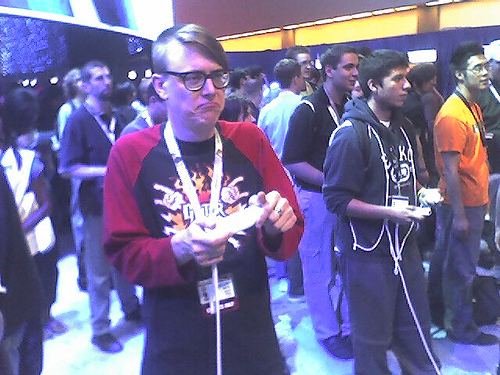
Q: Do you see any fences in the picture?
A: No, there are no fences.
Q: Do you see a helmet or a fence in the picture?
A: No, there are no fences or helmets.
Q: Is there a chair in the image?
A: No, there are no chairs.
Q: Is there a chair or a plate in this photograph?
A: No, there are no chairs or plates.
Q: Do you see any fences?
A: No, there are no fences.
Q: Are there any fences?
A: No, there are no fences.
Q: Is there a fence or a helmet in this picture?
A: No, there are no fences or helmets.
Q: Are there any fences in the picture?
A: No, there are no fences.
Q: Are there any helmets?
A: No, there are no helmets.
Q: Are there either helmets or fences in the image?
A: No, there are no helmets or fences.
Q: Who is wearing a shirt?
A: The man is wearing a shirt.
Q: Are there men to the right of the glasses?
A: Yes, there is a man to the right of the glasses.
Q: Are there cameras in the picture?
A: Yes, there is a camera.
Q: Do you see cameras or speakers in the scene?
A: Yes, there is a camera.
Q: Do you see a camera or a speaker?
A: Yes, there is a camera.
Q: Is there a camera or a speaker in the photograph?
A: Yes, there is a camera.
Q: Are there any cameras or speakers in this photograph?
A: Yes, there is a camera.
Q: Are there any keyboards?
A: No, there are no keyboards.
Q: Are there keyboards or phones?
A: No, there are no keyboards or phones.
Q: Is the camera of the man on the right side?
A: Yes, the camera is on the right of the image.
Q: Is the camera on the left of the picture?
A: No, the camera is on the right of the image.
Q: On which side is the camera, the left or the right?
A: The camera is on the right of the image.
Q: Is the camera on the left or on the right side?
A: The camera is on the right of the image.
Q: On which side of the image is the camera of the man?
A: The camera is on the right of the image.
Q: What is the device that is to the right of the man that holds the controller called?
A: The device is a camera.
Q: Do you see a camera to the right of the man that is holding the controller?
A: Yes, there is a camera to the right of the man.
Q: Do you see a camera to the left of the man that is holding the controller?
A: No, the camera is to the right of the man.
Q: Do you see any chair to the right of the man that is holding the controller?
A: No, there is a camera to the right of the man.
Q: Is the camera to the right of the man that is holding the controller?
A: Yes, the camera is to the right of the man.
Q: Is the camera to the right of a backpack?
A: No, the camera is to the right of the man.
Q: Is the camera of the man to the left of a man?
A: No, the camera is to the right of a man.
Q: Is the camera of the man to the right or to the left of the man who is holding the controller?
A: The camera is to the right of the man.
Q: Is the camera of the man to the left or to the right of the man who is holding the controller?
A: The camera is to the right of the man.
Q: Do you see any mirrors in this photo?
A: No, there are no mirrors.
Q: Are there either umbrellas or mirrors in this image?
A: No, there are no mirrors or umbrellas.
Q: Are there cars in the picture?
A: No, there are no cars.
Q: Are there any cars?
A: No, there are no cars.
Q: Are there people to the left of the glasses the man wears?
A: Yes, there are people to the left of the glasses.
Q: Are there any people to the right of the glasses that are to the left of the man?
A: No, the people are to the left of the glasses.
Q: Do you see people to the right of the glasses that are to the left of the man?
A: No, the people are to the left of the glasses.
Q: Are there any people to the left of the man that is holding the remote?
A: Yes, there are people to the left of the man.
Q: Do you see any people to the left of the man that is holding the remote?
A: Yes, there are people to the left of the man.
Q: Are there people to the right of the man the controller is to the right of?
A: No, the people are to the left of the man.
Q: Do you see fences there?
A: No, there are no fences.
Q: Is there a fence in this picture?
A: No, there are no fences.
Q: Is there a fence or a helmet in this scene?
A: No, there are no fences or helmets.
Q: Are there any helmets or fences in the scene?
A: No, there are no fences or helmets.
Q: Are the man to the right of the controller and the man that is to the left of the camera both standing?
A: Yes, both the man and the man are standing.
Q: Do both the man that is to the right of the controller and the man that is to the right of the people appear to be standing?
A: Yes, both the man and the man are standing.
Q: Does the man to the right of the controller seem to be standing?
A: Yes, the man is standing.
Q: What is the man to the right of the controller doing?
A: The man is standing.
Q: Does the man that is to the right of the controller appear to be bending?
A: No, the man is standing.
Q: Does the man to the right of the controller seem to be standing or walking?
A: The man is standing.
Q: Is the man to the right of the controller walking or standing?
A: The man is standing.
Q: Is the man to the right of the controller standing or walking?
A: The man is standing.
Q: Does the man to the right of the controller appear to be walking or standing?
A: The man is standing.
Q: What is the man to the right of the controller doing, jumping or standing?
A: The man is standing.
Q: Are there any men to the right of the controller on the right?
A: Yes, there is a man to the right of the controller.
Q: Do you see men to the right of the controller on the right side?
A: Yes, there is a man to the right of the controller.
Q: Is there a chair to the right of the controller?
A: No, there is a man to the right of the controller.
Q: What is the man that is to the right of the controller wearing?
A: The man is wearing a shirt.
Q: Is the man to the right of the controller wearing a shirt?
A: Yes, the man is wearing a shirt.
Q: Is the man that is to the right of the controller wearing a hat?
A: No, the man is wearing a shirt.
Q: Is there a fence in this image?
A: No, there are no fences.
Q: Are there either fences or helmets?
A: No, there are no fences or helmets.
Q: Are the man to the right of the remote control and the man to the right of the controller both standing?
A: Yes, both the man and the man are standing.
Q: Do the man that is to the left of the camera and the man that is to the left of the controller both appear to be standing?
A: Yes, both the man and the man are standing.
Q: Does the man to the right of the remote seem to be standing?
A: Yes, the man is standing.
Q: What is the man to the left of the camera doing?
A: The man is standing.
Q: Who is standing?
A: The man is standing.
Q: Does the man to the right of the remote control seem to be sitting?
A: No, the man is standing.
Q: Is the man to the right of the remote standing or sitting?
A: The man is standing.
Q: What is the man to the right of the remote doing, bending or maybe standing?
A: The man is standing.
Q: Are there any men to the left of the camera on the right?
A: Yes, there is a man to the left of the camera.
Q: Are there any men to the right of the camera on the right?
A: No, the man is to the left of the camera.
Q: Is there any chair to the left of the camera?
A: No, there is a man to the left of the camera.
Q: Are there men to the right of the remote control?
A: Yes, there is a man to the right of the remote control.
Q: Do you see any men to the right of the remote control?
A: Yes, there is a man to the right of the remote control.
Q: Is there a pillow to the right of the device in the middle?
A: No, there is a man to the right of the remote.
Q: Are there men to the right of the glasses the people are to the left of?
A: Yes, there is a man to the right of the glasses.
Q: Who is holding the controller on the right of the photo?
A: The man is holding the controller.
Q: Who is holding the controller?
A: The man is holding the controller.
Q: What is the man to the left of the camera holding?
A: The man is holding the controller.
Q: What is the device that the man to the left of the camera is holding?
A: The device is a controller.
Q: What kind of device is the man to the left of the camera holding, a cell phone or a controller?
A: The man is holding a controller.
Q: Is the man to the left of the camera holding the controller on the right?
A: Yes, the man is holding the controller.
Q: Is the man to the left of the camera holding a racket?
A: No, the man is holding the controller.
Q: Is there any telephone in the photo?
A: No, there are no phones.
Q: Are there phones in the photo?
A: No, there are no phones.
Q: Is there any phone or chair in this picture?
A: No, there are no phones or chairs.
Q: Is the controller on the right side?
A: Yes, the controller is on the right of the image.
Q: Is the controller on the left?
A: No, the controller is on the right of the image.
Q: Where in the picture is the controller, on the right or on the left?
A: The controller is on the right of the image.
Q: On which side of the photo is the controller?
A: The controller is on the right of the image.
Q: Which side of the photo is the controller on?
A: The controller is on the right of the image.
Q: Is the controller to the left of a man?
A: Yes, the controller is to the left of a man.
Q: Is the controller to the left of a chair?
A: No, the controller is to the left of a man.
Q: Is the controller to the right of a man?
A: No, the controller is to the left of a man.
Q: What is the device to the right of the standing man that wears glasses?
A: The device is a controller.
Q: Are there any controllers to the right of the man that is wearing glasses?
A: Yes, there is a controller to the right of the man.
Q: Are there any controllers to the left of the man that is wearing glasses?
A: No, the controller is to the right of the man.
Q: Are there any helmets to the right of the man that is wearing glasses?
A: No, there is a controller to the right of the man.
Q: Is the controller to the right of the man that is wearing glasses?
A: Yes, the controller is to the right of the man.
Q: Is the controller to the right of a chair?
A: No, the controller is to the right of the man.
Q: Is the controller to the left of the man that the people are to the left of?
A: No, the controller is to the right of the man.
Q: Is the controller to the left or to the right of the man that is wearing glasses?
A: The controller is to the right of the man.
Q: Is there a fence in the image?
A: No, there are no fences.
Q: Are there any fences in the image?
A: No, there are no fences.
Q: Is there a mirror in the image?
A: No, there are no mirrors.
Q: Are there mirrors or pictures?
A: No, there are no mirrors or pictures.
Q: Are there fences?
A: No, there are no fences.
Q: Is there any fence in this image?
A: No, there are no fences.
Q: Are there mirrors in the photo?
A: No, there are no mirrors.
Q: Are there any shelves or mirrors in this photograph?
A: No, there are no mirrors or shelves.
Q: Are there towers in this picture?
A: No, there are no towers.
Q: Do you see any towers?
A: No, there are no towers.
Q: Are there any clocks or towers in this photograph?
A: No, there are no towers or clocks.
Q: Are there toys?
A: No, there are no toys.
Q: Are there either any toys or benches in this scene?
A: No, there are no toys or benches.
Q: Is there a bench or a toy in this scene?
A: No, there are no toys or benches.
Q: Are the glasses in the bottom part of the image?
A: No, the glasses are in the top of the image.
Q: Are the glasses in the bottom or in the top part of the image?
A: The glasses are in the top of the image.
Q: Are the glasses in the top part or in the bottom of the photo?
A: The glasses are in the top of the image.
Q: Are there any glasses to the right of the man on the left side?
A: Yes, there are glasses to the right of the man.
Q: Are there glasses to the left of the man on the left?
A: No, the glasses are to the right of the man.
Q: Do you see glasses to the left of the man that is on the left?
A: No, the glasses are to the right of the man.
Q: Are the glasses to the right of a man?
A: Yes, the glasses are to the right of a man.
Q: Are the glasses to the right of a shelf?
A: No, the glasses are to the right of a man.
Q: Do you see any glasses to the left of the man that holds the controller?
A: Yes, there are glasses to the left of the man.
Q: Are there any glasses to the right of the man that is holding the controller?
A: No, the glasses are to the left of the man.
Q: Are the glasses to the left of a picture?
A: No, the glasses are to the left of the man.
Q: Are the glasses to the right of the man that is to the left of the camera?
A: No, the glasses are to the left of the man.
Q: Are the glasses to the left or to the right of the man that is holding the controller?
A: The glasses are to the left of the man.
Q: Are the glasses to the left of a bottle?
A: No, the glasses are to the left of a man.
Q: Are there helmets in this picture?
A: No, there are no helmets.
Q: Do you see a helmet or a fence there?
A: No, there are no helmets or fences.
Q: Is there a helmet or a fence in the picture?
A: No, there are no helmets or fences.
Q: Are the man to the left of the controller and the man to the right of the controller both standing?
A: Yes, both the man and the man are standing.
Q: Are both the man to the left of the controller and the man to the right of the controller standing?
A: Yes, both the man and the man are standing.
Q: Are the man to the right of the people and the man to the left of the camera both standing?
A: Yes, both the man and the man are standing.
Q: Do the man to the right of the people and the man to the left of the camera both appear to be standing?
A: Yes, both the man and the man are standing.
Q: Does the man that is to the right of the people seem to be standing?
A: Yes, the man is standing.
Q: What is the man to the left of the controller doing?
A: The man is standing.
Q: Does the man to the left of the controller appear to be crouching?
A: No, the man is standing.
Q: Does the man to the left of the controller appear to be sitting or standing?
A: The man is standing.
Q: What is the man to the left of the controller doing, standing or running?
A: The man is standing.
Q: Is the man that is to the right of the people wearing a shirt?
A: Yes, the man is wearing a shirt.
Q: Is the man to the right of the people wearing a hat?
A: No, the man is wearing a shirt.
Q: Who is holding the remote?
A: The man is holding the remote.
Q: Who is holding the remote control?
A: The man is holding the remote.